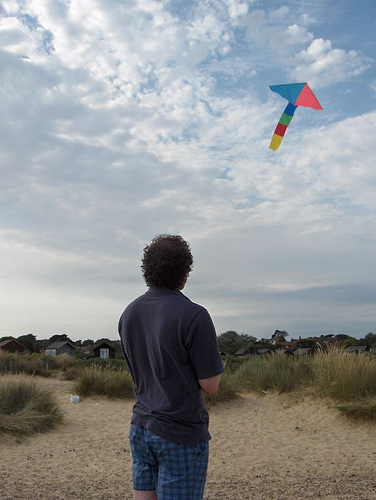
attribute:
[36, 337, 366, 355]
huts — small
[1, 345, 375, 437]
grass — green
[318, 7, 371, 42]
sky — blue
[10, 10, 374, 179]
clouds — white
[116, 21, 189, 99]
clouds — fluffy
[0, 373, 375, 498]
sand — tan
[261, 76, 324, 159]
kite — pink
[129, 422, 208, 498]
short — blue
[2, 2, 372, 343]
sky — is blue, cloudy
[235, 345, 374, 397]
tall grass — green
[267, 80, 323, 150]
kite — pink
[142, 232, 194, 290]
hair — curly